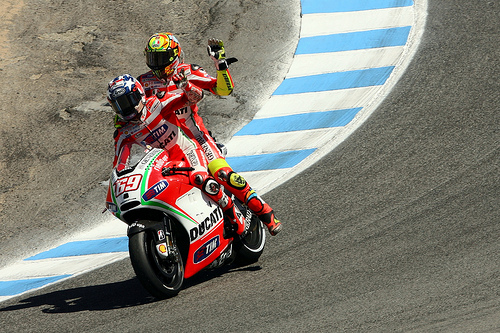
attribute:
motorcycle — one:
[105, 158, 273, 289]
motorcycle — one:
[106, 153, 263, 294]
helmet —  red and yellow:
[127, 99, 192, 106]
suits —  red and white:
[153, 99, 208, 193]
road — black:
[269, 161, 468, 333]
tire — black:
[136, 209, 164, 306]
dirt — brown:
[22, 131, 64, 246]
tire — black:
[239, 205, 274, 265]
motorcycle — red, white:
[98, 140, 268, 297]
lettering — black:
[188, 205, 223, 242]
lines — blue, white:
[265, 0, 417, 95]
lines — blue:
[291, 23, 381, 136]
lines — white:
[299, 52, 392, 77]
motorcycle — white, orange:
[114, 146, 296, 287]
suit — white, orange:
[120, 114, 209, 199]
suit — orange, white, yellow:
[156, 77, 221, 132]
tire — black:
[122, 214, 192, 290]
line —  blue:
[0, 274, 81, 303]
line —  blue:
[24, 239, 134, 264]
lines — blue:
[250, 64, 391, 110]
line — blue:
[273, 60, 402, 91]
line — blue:
[226, 147, 317, 171]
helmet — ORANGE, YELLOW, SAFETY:
[142, 30, 181, 72]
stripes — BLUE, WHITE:
[37, 9, 429, 278]